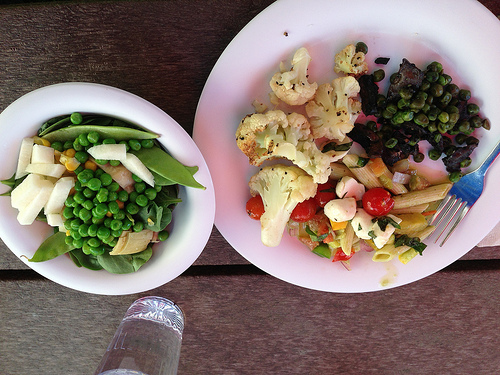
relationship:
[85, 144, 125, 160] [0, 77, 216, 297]
vegetables in bowl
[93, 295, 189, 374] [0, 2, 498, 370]
glass on table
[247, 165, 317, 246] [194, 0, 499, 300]
cauliflower on plate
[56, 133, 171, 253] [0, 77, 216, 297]
peas in bowl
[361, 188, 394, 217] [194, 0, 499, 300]
tomato on plate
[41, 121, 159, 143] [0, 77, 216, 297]
snap pea in bowl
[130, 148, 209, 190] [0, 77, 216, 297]
snap pea in bowl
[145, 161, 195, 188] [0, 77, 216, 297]
snap pea in bowl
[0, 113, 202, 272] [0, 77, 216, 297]
vegetables in bowl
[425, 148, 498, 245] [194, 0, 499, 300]
fork on plate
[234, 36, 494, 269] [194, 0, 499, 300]
food on plate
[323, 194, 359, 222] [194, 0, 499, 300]
cheese on plate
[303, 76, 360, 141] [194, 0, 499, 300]
food on plate